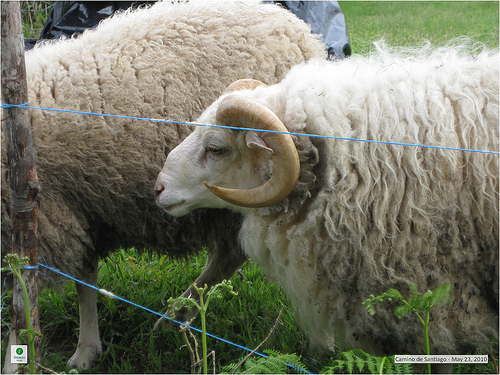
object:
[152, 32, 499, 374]
sheep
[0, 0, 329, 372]
sheep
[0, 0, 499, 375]
fence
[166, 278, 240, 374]
weed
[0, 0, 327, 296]
wool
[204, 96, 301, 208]
horns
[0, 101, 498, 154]
wire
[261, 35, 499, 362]
hair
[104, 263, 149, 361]
grass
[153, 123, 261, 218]
face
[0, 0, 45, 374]
fencepost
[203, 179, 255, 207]
tip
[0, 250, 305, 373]
ground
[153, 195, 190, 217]
mouth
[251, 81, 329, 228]
neck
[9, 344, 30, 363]
sticker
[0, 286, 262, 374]
shade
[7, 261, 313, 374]
rope